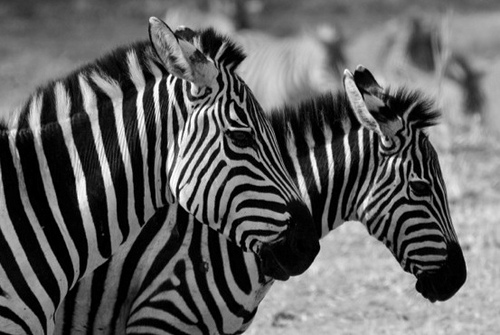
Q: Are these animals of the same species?
A: Yes, all the animals are zebras.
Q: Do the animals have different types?
A: No, all the animals are zebras.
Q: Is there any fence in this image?
A: No, there are no fences.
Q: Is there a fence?
A: No, there are no fences.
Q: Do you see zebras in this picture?
A: Yes, there is a zebra.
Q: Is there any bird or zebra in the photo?
A: Yes, there is a zebra.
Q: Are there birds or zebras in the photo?
A: Yes, there is a zebra.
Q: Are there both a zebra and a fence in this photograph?
A: No, there is a zebra but no fences.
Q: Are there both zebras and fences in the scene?
A: No, there is a zebra but no fences.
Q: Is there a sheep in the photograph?
A: No, there is no sheep.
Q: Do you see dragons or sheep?
A: No, there are no sheep or dragons.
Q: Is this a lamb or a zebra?
A: This is a zebra.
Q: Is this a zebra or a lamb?
A: This is a zebra.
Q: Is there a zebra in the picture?
A: Yes, there is a zebra.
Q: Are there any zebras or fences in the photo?
A: Yes, there is a zebra.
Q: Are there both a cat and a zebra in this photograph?
A: No, there is a zebra but no cats.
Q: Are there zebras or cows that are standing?
A: Yes, the zebra is standing.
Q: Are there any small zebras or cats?
A: Yes, there is a small zebra.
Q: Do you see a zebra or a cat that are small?
A: Yes, the zebra is small.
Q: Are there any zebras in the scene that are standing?
A: Yes, there is a zebra that is standing.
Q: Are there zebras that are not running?
A: Yes, there is a zebra that is standing.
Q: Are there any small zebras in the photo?
A: Yes, there is a small zebra.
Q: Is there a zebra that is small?
A: Yes, there is a zebra that is small.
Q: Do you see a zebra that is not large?
A: Yes, there is a small zebra.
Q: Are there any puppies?
A: No, there are no puppies.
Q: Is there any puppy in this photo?
A: No, there are no puppies.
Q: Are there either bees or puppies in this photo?
A: No, there are no puppies or bees.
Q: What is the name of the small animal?
A: The animal is a zebra.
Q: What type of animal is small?
A: The animal is a zebra.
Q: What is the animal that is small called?
A: The animal is a zebra.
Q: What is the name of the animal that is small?
A: The animal is a zebra.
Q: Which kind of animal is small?
A: The animal is a zebra.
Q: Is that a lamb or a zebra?
A: That is a zebra.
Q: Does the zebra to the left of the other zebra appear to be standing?
A: Yes, the zebra is standing.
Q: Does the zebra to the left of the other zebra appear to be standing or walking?
A: The zebra is standing.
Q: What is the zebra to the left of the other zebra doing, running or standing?
A: The zebra is standing.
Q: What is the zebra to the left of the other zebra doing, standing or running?
A: The zebra is standing.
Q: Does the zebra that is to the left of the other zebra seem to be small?
A: Yes, the zebra is small.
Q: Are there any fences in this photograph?
A: No, there are no fences.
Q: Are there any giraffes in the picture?
A: No, there are no giraffes.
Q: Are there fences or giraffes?
A: No, there are no giraffes or fences.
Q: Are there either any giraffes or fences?
A: No, there are no giraffes or fences.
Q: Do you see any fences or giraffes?
A: No, there are no giraffes or fences.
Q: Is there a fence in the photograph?
A: No, there are no fences.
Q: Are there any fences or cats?
A: No, there are no fences or cats.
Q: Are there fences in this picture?
A: No, there are no fences.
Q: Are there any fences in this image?
A: No, there are no fences.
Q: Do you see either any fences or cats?
A: No, there are no fences or cats.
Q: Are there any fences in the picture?
A: No, there are no fences.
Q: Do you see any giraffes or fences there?
A: No, there are no fences or giraffes.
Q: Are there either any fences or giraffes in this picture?
A: No, there are no fences or giraffes.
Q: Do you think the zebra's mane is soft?
A: Yes, the mane is soft.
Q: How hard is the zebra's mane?
A: The mane is soft.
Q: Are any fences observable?
A: No, there are no fences.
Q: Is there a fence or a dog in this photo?
A: No, there are no fences or dogs.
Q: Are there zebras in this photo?
A: Yes, there are zebras.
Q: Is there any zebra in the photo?
A: Yes, there are zebras.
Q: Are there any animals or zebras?
A: Yes, there are zebras.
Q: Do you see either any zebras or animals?
A: Yes, there are zebras.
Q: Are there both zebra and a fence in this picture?
A: No, there are zebras but no fences.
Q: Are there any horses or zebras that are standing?
A: Yes, the zebras are standing.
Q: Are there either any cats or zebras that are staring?
A: Yes, the zebras are staring.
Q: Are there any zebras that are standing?
A: Yes, there are zebras that are standing.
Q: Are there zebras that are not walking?
A: Yes, there are zebras that are standing.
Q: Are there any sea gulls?
A: No, there are no sea gulls.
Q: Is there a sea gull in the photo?
A: No, there are no seagulls.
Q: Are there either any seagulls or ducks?
A: No, there are no seagulls or ducks.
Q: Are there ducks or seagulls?
A: No, there are no seagulls or ducks.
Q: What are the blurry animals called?
A: The animals are zebras.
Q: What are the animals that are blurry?
A: The animals are zebras.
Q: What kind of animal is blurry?
A: The animal is zebras.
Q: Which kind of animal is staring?
A: The animal is zebras.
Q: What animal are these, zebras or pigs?
A: These are zebras.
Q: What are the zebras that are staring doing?
A: The zebras are standing.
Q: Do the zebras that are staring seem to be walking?
A: No, the zebras are standing.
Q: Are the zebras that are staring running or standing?
A: The zebras are standing.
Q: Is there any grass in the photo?
A: Yes, there is grass.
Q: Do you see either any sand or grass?
A: Yes, there is grass.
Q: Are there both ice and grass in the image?
A: No, there is grass but no ice.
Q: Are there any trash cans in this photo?
A: No, there are no trash cans.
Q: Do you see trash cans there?
A: No, there are no trash cans.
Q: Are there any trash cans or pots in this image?
A: No, there are no trash cans or pots.